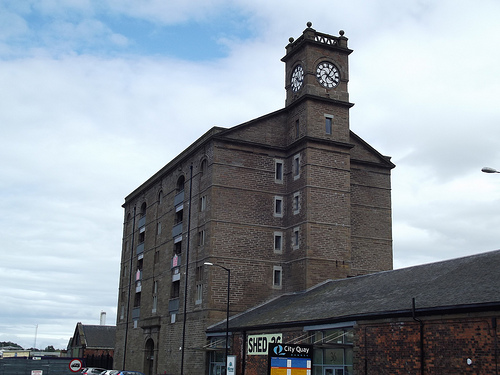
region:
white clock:
[315, 58, 347, 97]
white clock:
[281, 58, 319, 102]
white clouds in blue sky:
[22, 23, 67, 80]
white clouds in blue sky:
[48, 0, 92, 37]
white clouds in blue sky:
[37, 128, 64, 167]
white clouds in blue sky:
[76, 43, 140, 107]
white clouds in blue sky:
[364, 39, 401, 94]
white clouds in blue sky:
[420, 43, 477, 91]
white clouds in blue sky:
[401, 90, 448, 152]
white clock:
[302, 61, 339, 99]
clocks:
[285, 29, 343, 104]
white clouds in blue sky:
[34, 43, 76, 73]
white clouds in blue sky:
[70, 79, 108, 114]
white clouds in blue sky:
[50, 159, 90, 181]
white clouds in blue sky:
[44, 202, 78, 240]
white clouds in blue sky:
[388, 39, 432, 79]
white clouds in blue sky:
[385, 62, 430, 103]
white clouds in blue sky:
[34, 221, 91, 276]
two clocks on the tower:
[285, 60, 340, 93]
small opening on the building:
[272, 159, 283, 185]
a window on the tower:
[324, 116, 333, 135]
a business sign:
[265, 340, 315, 373]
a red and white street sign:
[67, 358, 81, 373]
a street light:
[202, 260, 231, 372]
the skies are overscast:
[7, 8, 494, 341]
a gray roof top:
[205, 251, 498, 333]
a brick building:
[357, 322, 499, 372]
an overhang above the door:
[192, 336, 227, 354]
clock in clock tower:
[304, 48, 334, 95]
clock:
[287, 59, 311, 100]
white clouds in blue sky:
[60, 62, 130, 104]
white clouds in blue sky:
[395, 79, 437, 124]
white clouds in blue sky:
[60, 43, 115, 88]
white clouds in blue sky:
[168, 46, 238, 106]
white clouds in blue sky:
[21, 105, 51, 140]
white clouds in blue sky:
[50, 162, 91, 204]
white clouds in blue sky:
[25, 198, 55, 240]